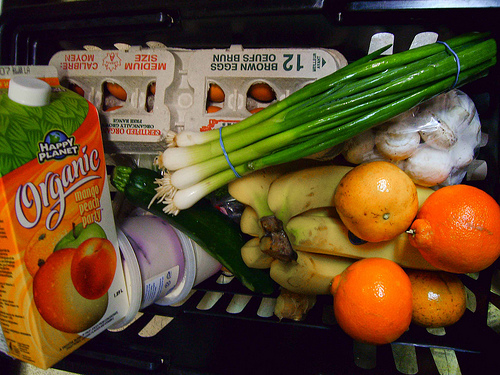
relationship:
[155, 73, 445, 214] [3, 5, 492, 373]
onions in basket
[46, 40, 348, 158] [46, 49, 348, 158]
eggs in basket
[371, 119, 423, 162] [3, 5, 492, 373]
vegetable in basket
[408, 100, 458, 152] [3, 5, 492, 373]
vegetable in basket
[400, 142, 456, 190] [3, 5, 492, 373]
vegetable in basket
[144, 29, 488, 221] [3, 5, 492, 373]
vegetable in basket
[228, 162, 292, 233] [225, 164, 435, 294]
banana in banana bundle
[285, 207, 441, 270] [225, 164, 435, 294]
banana in banana bundle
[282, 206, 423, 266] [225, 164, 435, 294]
banana in banana bundle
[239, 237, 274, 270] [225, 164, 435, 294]
banana in banana bundle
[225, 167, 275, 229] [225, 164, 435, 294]
banana in banana bundle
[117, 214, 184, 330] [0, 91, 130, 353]
tub next to juice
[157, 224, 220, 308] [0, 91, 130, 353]
tub next to juice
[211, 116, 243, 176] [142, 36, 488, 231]
rubber band wrapped around onion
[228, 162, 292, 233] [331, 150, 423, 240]
banana next to orange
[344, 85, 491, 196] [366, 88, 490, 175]
mushrooms in a bag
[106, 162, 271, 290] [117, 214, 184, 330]
zucchini on top of tub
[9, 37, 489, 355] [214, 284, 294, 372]
groceries in container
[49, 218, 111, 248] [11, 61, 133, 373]
apple on carton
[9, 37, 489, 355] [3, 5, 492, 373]
groceries in basket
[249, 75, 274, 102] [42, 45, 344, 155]
egg in carton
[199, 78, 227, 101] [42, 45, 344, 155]
egg in carton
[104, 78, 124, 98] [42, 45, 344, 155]
egg in carton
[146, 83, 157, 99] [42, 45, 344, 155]
egg in carton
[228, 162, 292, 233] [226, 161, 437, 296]
banana in bunch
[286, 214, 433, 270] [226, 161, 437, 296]
banana in bunch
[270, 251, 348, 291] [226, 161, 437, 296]
banana in bunch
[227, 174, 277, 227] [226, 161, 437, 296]
banana in bunch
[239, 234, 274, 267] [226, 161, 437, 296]
banana in bunch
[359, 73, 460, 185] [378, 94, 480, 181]
mushrooms in bag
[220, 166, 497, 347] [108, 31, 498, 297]
fruits and vegetables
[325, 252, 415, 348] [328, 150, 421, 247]
orange with orange